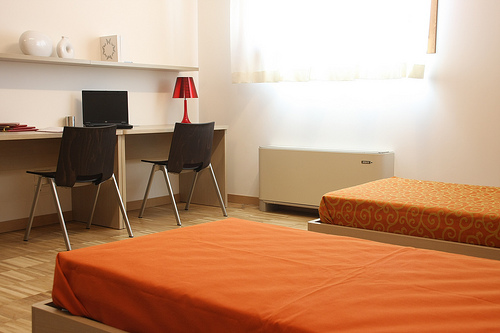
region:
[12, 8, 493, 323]
modern and spare bedroom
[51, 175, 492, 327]
beds crisply covered in orange fabric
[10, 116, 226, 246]
black chairs pushed under desks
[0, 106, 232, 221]
table top and supporting panels against the white wall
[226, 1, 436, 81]
plain white curtain covering bright window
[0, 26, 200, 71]
ceramics and books on long shelf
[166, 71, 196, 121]
shiny red lampshade on thin and curved red base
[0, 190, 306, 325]
wooden floor in square and rectangle patterns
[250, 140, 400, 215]
rectangular white unit below window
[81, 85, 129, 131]
black laptop with open lid on table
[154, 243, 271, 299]
orange sheet on the bed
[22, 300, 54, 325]
box spring underneath the bed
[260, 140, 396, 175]
heater up against the wall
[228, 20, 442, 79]
curtain on the window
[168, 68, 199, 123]
red lamp on the table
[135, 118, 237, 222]
chair next to the desk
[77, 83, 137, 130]
laptop on the desk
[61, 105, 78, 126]
cup on the desk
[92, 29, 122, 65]
scuplture on the desk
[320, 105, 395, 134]
white wall in the room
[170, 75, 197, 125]
Red lamp on a desk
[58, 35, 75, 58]
White vase on a shelf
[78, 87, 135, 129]
Black laptop on a shelf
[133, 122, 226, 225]
Black chair at a desk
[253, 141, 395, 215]
Air conditioning unit in a room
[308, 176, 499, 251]
Single bed in a room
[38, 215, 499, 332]
Red sheet on a bed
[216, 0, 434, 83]
White sheet over a window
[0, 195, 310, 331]
Wood on the floor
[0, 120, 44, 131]
Red folder on a desk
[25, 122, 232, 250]
Two black chairs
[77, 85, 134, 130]
Black computer on top of desk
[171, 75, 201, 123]
Red lamp on the desk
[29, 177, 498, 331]
Two beds next to each other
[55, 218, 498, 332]
Orange bed sheet on the bed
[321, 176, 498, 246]
Yellow pattern on orange bed sheet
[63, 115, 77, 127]
Cup on the table next to computer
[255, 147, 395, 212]
White radiator under window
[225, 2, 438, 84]
White curtain covering window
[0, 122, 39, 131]
Red plates on the desk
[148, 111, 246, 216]
chair next to desk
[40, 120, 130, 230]
chair next to desk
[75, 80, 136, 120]
lap top on a desk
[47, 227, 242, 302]
bed in a room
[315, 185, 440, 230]
bed in a room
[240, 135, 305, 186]
ac unit next to wall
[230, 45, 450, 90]
curtain on a window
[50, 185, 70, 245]
leg of a chair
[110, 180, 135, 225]
leg of a chair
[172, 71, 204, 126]
lamp on a desk